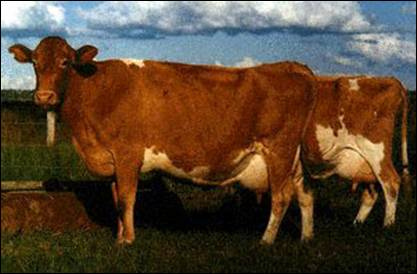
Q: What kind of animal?
A: Cow.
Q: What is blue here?
A: The sky.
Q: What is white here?
A: The clouds.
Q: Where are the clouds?
A: In the sky.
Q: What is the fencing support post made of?
A: Wood.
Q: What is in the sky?
A: Clouds.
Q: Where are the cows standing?
A: In the grass.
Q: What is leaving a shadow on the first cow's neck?
A: It's ear.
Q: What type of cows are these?
A: Milking cows.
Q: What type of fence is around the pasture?
A: Barbed wire.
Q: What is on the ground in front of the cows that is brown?
A: A mound of dirt.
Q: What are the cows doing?
A: Grazing.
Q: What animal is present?
A: Cows.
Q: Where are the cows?
A: Standing in grass.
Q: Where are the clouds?
A: In sky.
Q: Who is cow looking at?
A: At the camera.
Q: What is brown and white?
A: Cow.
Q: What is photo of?
A: Two cows.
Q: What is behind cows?
A: Fence.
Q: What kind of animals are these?
A: Cows.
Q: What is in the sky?
A: Clouds.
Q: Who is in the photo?
A: Nobody.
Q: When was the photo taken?
A: Daytime.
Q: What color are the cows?
A: Brown and white.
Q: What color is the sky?
A: Blue with white clouds.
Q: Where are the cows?
A: In front of a fence.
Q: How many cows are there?
A: Two.